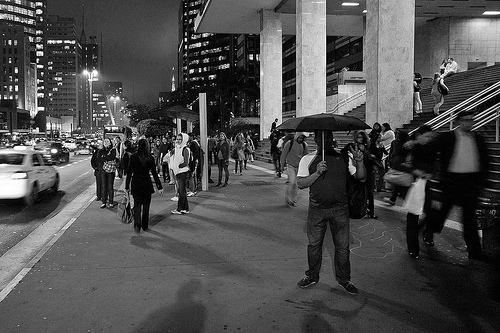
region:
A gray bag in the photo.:
[120, 205, 134, 230]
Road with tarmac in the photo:
[186, 229, 266, 305]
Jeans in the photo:
[306, 207, 352, 280]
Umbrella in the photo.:
[281, 102, 371, 159]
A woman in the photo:
[115, 134, 165, 233]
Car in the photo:
[0, 144, 63, 207]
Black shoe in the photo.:
[295, 271, 325, 287]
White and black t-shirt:
[298, 158, 345, 210]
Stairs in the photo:
[453, 66, 490, 92]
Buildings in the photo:
[182, 2, 320, 92]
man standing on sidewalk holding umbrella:
[281, 111, 371, 296]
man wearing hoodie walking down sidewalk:
[280, 132, 308, 208]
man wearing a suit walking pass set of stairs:
[423, 108, 495, 265]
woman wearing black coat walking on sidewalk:
[114, 140, 161, 231]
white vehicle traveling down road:
[0, 146, 61, 201]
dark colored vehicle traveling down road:
[29, 141, 72, 158]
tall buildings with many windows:
[45, 17, 80, 142]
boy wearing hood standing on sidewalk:
[172, 132, 191, 214]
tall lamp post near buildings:
[82, 69, 97, 129]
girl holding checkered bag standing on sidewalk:
[100, 140, 116, 206]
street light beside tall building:
[82, 67, 102, 82]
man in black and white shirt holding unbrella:
[279, 113, 373, 188]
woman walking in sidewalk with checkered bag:
[99, 137, 117, 208]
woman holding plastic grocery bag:
[407, 127, 435, 219]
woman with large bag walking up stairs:
[432, 70, 448, 115]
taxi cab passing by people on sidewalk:
[0, 144, 60, 194]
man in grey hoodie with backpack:
[282, 131, 310, 203]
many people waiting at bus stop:
[169, 110, 204, 187]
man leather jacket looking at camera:
[214, 131, 231, 188]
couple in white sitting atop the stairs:
[439, 56, 460, 72]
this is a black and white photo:
[21, 13, 484, 276]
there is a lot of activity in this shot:
[87, 114, 454, 270]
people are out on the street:
[87, 125, 249, 210]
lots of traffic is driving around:
[0, 109, 97, 201]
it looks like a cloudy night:
[26, 3, 210, 118]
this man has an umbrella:
[270, 101, 368, 209]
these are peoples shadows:
[120, 272, 339, 331]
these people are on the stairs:
[414, 53, 499, 127]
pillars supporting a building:
[235, 16, 422, 116]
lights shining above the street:
[72, 63, 123, 125]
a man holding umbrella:
[269, 107, 371, 297]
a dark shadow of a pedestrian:
[128, 266, 218, 332]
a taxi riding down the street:
[2, 138, 58, 214]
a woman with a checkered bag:
[88, 133, 119, 209]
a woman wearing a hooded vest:
[168, 128, 196, 218]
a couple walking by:
[390, 111, 498, 265]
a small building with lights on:
[3, 22, 35, 122]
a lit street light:
[81, 66, 98, 127]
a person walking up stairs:
[428, 62, 449, 119]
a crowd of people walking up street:
[206, 131, 258, 191]